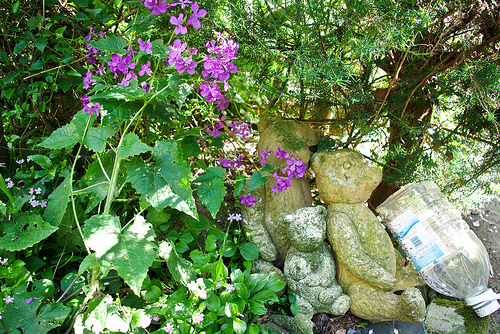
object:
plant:
[1, 1, 304, 333]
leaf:
[85, 214, 160, 296]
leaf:
[0, 211, 58, 252]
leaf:
[41, 173, 70, 228]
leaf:
[125, 141, 199, 219]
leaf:
[0, 292, 71, 333]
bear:
[310, 148, 426, 323]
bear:
[242, 120, 323, 296]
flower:
[188, 2, 206, 29]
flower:
[171, 14, 189, 35]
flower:
[145, 0, 166, 14]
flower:
[171, 40, 188, 56]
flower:
[202, 60, 225, 79]